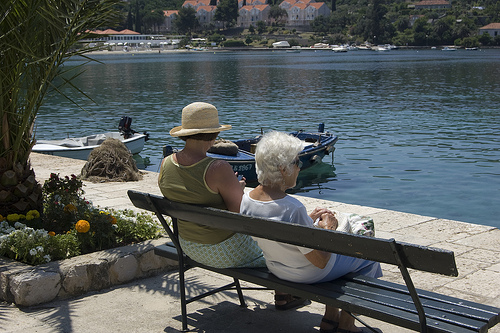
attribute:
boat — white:
[35, 127, 148, 155]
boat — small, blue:
[30, 128, 150, 166]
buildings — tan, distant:
[158, 0, 327, 30]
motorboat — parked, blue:
[182, 125, 341, 180]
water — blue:
[31, 51, 482, 235]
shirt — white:
[241, 191, 337, 283]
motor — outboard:
[115, 115, 136, 140]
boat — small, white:
[47, 103, 182, 195]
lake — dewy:
[29, 0, 498, 102]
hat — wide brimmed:
[151, 70, 268, 166]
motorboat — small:
[42, 122, 145, 159]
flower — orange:
[70, 216, 93, 234]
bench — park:
[147, 197, 458, 331]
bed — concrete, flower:
[12, 184, 124, 258]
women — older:
[148, 96, 419, 286]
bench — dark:
[115, 173, 495, 331]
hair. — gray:
[250, 119, 303, 184]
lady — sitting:
[224, 133, 354, 251]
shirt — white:
[235, 187, 338, 282]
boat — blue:
[256, 108, 358, 164]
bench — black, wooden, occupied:
[125, 189, 497, 330]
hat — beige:
[169, 95, 232, 135]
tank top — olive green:
[158, 151, 239, 241]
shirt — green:
[160, 159, 224, 239]